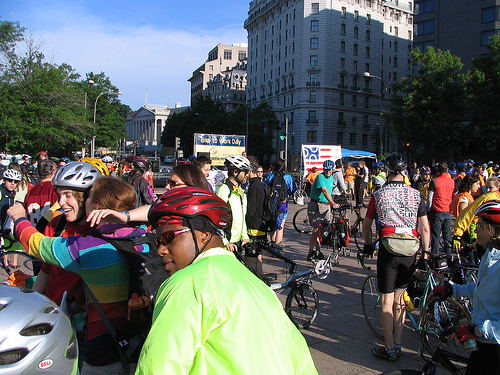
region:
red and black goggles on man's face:
[131, 220, 228, 253]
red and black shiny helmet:
[130, 163, 266, 229]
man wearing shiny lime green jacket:
[140, 262, 324, 369]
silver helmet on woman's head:
[48, 152, 113, 192]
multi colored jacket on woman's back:
[11, 215, 150, 290]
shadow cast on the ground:
[295, 267, 427, 364]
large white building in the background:
[267, 21, 388, 95]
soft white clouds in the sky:
[85, 24, 172, 56]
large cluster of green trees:
[16, 59, 136, 154]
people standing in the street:
[33, 145, 410, 271]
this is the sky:
[84, 3, 236, 35]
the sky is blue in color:
[173, 6, 219, 29]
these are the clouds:
[121, 36, 188, 76]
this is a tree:
[406, 57, 468, 139]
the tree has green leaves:
[411, 85, 434, 107]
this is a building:
[282, 14, 354, 133]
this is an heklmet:
[161, 190, 226, 221]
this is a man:
[367, 171, 416, 363]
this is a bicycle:
[276, 252, 323, 299]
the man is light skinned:
[383, 307, 390, 324]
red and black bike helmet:
[145, 168, 245, 249]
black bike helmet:
[377, 142, 417, 179]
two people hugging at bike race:
[15, 154, 157, 345]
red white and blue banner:
[294, 131, 351, 192]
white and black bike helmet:
[220, 143, 260, 190]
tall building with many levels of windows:
[249, 11, 439, 195]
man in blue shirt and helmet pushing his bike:
[297, 148, 354, 279]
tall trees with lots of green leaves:
[10, 31, 157, 221]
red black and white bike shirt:
[351, 174, 446, 286]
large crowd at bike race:
[22, 146, 495, 336]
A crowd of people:
[47, 128, 462, 326]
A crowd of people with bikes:
[49, 155, 458, 328]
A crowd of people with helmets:
[53, 137, 471, 324]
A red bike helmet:
[135, 179, 260, 274]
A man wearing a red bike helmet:
[135, 169, 254, 278]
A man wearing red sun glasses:
[131, 180, 272, 285]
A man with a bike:
[363, 155, 460, 373]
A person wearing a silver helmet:
[40, 150, 100, 237]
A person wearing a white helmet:
[213, 145, 255, 220]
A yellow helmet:
[70, 142, 129, 192]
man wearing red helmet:
[141, 184, 315, 374]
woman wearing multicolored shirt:
[7, 176, 163, 354]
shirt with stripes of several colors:
[11, 216, 157, 354]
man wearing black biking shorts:
[363, 150, 431, 289]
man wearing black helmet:
[377, 150, 414, 184]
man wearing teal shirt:
[311, 160, 339, 243]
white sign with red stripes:
[302, 138, 347, 184]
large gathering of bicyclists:
[372, 152, 497, 267]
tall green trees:
[0, 26, 146, 150]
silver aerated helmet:
[1, 279, 80, 371]